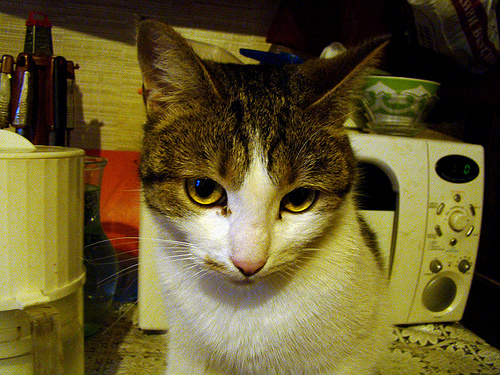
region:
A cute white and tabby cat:
[135, 19, 397, 374]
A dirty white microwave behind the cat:
[137, 109, 484, 331]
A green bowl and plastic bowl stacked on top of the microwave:
[350, 75, 437, 133]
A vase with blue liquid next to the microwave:
[55, 155, 118, 335]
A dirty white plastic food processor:
[0, 140, 85, 373]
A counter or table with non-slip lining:
[82, 295, 498, 372]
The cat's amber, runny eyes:
[180, 172, 325, 218]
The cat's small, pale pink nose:
[230, 257, 267, 276]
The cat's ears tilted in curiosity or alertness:
[134, 16, 389, 124]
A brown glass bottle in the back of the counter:
[20, 8, 60, 144]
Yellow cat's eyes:
[154, 155, 336, 230]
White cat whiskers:
[111, 227, 371, 311]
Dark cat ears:
[109, 12, 409, 89]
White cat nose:
[225, 236, 291, 278]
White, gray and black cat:
[124, 89, 369, 314]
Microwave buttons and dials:
[372, 131, 477, 331]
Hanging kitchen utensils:
[0, 23, 95, 176]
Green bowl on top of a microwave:
[365, 67, 450, 147]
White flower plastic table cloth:
[63, 323, 478, 363]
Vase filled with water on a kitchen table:
[70, 137, 144, 349]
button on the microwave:
[420, 273, 458, 318]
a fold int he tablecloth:
[437, 324, 491, 374]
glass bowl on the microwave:
[355, 76, 447, 142]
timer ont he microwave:
[432, 152, 481, 191]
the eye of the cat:
[183, 164, 228, 209]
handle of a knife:
[47, 55, 71, 127]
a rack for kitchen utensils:
[3, 54, 85, 139]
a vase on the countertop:
[82, 155, 118, 337]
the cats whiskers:
[77, 231, 202, 328]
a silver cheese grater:
[16, 4, 61, 60]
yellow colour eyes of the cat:
[172, 162, 338, 232]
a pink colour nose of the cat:
[228, 243, 277, 283]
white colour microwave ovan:
[377, 135, 474, 325]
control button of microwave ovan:
[418, 155, 481, 326]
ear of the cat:
[131, 12, 386, 129]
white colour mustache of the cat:
[151, 235, 344, 290]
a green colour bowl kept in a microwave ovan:
[338, 67, 439, 132]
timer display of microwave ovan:
[432, 147, 481, 189]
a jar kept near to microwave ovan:
[80, 157, 120, 309]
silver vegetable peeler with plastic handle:
[22, 12, 57, 57]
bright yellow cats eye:
[185, 167, 330, 225]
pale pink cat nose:
[229, 254, 271, 285]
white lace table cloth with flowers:
[408, 317, 497, 372]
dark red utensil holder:
[15, 14, 90, 148]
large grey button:
[424, 267, 478, 330]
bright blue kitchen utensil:
[235, 29, 310, 64]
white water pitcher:
[2, 145, 79, 368]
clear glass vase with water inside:
[88, 151, 128, 336]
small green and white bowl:
[364, 73, 451, 133]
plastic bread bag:
[414, 1, 499, 69]